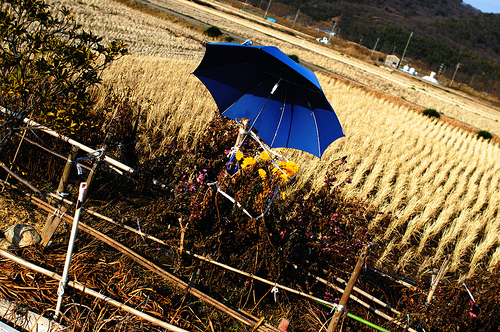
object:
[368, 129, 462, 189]
crops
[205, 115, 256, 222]
pole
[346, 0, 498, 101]
mountain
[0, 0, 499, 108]
background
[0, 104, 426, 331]
fence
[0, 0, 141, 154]
plant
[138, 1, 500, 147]
road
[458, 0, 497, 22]
sky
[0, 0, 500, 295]
field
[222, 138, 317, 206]
flowers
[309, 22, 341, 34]
buildings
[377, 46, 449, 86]
cluster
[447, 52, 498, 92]
trees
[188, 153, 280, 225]
bunch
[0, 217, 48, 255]
rock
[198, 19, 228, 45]
bush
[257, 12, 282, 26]
building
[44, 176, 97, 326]
posts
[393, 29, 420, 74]
electrical pole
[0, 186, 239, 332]
dry grass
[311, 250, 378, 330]
pole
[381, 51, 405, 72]
barn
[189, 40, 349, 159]
spokes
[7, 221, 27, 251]
shadow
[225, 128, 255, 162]
handle